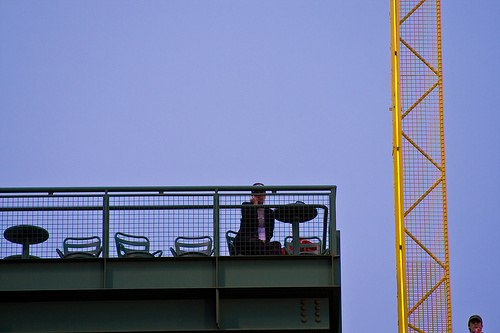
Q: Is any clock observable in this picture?
A: No, there are no clocks.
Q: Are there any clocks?
A: No, there are no clocks.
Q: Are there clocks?
A: No, there are no clocks.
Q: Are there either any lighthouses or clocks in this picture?
A: No, there are no clocks or lighthouses.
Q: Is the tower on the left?
A: No, the tower is on the right of the image.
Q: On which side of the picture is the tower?
A: The tower is on the right of the image.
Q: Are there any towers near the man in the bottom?
A: Yes, there is a tower near the man.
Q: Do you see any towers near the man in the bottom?
A: Yes, there is a tower near the man.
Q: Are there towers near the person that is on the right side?
A: Yes, there is a tower near the man.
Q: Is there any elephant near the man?
A: No, there is a tower near the man.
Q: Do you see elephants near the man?
A: No, there is a tower near the man.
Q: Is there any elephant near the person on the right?
A: No, there is a tower near the man.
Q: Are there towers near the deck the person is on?
A: Yes, there is a tower near the deck.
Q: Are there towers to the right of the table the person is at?
A: Yes, there is a tower to the right of the table.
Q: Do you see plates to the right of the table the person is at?
A: No, there is a tower to the right of the table.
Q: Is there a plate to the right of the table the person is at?
A: No, there is a tower to the right of the table.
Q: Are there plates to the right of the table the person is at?
A: No, there is a tower to the right of the table.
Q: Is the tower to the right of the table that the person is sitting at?
A: Yes, the tower is to the right of the table.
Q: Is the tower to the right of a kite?
A: No, the tower is to the right of the table.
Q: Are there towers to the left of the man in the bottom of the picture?
A: Yes, there is a tower to the left of the man.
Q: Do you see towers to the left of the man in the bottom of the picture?
A: Yes, there is a tower to the left of the man.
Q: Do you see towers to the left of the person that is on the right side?
A: Yes, there is a tower to the left of the man.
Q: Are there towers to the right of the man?
A: No, the tower is to the left of the man.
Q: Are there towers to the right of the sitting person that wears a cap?
A: No, the tower is to the left of the man.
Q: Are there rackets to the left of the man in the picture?
A: No, there is a tower to the left of the man.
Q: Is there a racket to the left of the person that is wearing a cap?
A: No, there is a tower to the left of the man.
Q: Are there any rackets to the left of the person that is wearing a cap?
A: No, there is a tower to the left of the man.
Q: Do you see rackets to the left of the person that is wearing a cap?
A: No, there is a tower to the left of the man.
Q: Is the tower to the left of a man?
A: Yes, the tower is to the left of a man.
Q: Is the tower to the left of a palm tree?
A: No, the tower is to the left of a man.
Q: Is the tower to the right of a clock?
A: No, the tower is to the right of the fence.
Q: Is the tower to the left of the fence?
A: No, the tower is to the right of the fence.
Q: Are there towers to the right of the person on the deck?
A: Yes, there is a tower to the right of the person.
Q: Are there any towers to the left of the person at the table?
A: No, the tower is to the right of the person.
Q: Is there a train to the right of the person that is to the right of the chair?
A: No, there is a tower to the right of the person.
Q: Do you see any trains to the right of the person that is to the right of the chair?
A: No, there is a tower to the right of the person.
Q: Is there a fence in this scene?
A: Yes, there is a fence.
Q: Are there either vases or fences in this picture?
A: Yes, there is a fence.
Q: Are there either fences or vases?
A: Yes, there is a fence.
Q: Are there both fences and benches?
A: No, there is a fence but no benches.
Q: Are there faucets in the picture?
A: No, there are no faucets.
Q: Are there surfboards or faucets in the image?
A: No, there are no faucets or surfboards.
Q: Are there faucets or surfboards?
A: No, there are no faucets or surfboards.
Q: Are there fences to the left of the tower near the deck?
A: Yes, there is a fence to the left of the tower.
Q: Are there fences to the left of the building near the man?
A: Yes, there is a fence to the left of the tower.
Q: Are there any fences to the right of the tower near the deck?
A: No, the fence is to the left of the tower.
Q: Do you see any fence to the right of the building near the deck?
A: No, the fence is to the left of the tower.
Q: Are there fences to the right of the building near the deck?
A: No, the fence is to the left of the tower.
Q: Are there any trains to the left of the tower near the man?
A: No, there is a fence to the left of the tower.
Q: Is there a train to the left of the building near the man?
A: No, there is a fence to the left of the tower.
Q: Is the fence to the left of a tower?
A: Yes, the fence is to the left of a tower.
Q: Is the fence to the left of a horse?
A: No, the fence is to the left of a tower.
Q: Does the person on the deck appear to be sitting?
A: Yes, the person is sitting.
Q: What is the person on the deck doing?
A: The person is sitting.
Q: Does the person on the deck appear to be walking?
A: No, the person is sitting.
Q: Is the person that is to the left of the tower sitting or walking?
A: The person is sitting.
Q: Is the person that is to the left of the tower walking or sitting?
A: The person is sitting.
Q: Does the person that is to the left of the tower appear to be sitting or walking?
A: The person is sitting.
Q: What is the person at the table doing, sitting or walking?
A: The person is sitting.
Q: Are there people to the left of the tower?
A: Yes, there is a person to the left of the tower.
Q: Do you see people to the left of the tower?
A: Yes, there is a person to the left of the tower.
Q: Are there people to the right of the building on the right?
A: No, the person is to the left of the tower.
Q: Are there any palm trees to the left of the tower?
A: No, there is a person to the left of the tower.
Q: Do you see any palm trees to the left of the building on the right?
A: No, there is a person to the left of the tower.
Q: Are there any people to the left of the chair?
A: No, the person is to the right of the chair.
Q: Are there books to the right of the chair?
A: No, there is a person to the right of the chair.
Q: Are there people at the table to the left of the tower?
A: Yes, there is a person at the table.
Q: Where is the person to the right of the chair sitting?
A: The person is sitting at the table.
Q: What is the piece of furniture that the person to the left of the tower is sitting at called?
A: The piece of furniture is a table.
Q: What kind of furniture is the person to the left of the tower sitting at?
A: The person is sitting at the table.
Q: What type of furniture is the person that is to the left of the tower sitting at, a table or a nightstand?
A: The person is sitting at a table.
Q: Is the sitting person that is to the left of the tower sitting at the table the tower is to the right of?
A: Yes, the person is sitting at the table.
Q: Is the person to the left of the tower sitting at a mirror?
A: No, the person is sitting at the table.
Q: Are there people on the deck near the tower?
A: Yes, there is a person on the deck.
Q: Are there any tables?
A: Yes, there is a table.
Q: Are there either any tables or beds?
A: Yes, there is a table.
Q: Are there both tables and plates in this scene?
A: No, there is a table but no plates.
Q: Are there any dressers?
A: No, there are no dressers.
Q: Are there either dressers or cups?
A: No, there are no dressers or cups.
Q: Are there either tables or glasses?
A: Yes, there is a table.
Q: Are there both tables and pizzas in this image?
A: No, there is a table but no pizzas.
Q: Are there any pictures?
A: No, there are no pictures.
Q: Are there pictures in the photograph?
A: No, there are no pictures.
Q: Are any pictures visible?
A: No, there are no pictures.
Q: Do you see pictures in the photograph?
A: No, there are no pictures.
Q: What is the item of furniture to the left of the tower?
A: The piece of furniture is a table.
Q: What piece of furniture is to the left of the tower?
A: The piece of furniture is a table.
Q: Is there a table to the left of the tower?
A: Yes, there is a table to the left of the tower.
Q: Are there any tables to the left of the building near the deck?
A: Yes, there is a table to the left of the tower.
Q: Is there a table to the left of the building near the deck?
A: Yes, there is a table to the left of the tower.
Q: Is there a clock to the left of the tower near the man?
A: No, there is a table to the left of the tower.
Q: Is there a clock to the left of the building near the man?
A: No, there is a table to the left of the tower.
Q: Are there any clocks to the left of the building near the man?
A: No, there is a table to the left of the tower.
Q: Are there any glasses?
A: No, there are no glasses.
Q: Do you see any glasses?
A: No, there are no glasses.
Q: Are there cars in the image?
A: No, there are no cars.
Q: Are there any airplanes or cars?
A: No, there are no cars or airplanes.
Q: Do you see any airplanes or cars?
A: No, there are no cars or airplanes.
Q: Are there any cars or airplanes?
A: No, there are no cars or airplanes.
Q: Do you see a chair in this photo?
A: Yes, there is a chair.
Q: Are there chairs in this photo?
A: Yes, there is a chair.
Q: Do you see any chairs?
A: Yes, there is a chair.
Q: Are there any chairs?
A: Yes, there is a chair.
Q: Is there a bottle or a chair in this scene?
A: Yes, there is a chair.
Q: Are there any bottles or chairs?
A: Yes, there is a chair.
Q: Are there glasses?
A: No, there are no glasses.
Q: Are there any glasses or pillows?
A: No, there are no glasses or pillows.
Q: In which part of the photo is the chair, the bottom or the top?
A: The chair is in the bottom of the image.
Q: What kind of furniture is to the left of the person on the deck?
A: The piece of furniture is a chair.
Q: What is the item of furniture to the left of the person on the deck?
A: The piece of furniture is a chair.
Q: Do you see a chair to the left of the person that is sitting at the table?
A: Yes, there is a chair to the left of the person.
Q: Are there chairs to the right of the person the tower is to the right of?
A: No, the chair is to the left of the person.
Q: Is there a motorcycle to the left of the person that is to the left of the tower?
A: No, there is a chair to the left of the person.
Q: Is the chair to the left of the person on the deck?
A: Yes, the chair is to the left of the person.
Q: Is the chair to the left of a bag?
A: No, the chair is to the left of the person.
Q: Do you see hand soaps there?
A: No, there are no hand soaps.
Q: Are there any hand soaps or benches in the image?
A: No, there are no hand soaps or benches.